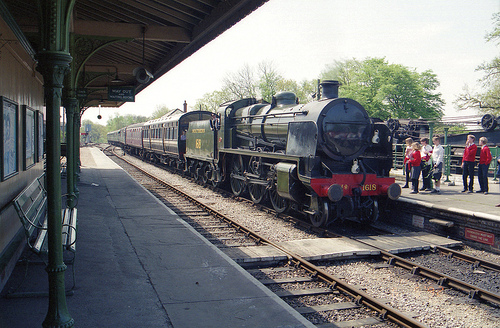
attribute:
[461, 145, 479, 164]
shirt — red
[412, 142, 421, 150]
hair — blonde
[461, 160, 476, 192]
pants — black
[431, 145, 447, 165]
shirt — white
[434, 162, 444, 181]
shorts — dark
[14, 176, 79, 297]
bench — back, sitting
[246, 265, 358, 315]
slats — wooden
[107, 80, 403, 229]
train — sitting, red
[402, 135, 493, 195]
people — waiting, three, wearing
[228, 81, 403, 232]
engine — black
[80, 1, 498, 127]
sky — gray